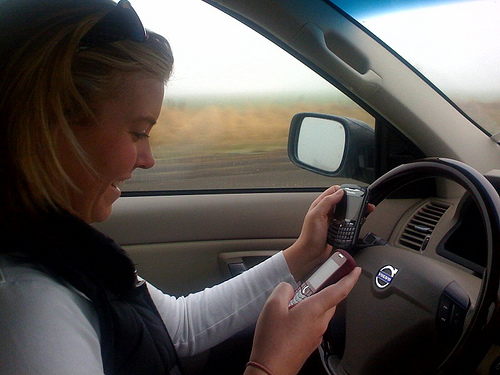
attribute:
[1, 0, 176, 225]
head —  woman's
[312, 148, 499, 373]
steering wheel —  car's, for steering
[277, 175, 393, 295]
phones — cell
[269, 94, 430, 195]
mirror —  of    car, to  side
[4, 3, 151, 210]
hair — blonde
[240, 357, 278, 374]
tie — hair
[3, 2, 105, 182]
hair — light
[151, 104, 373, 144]
grass — dead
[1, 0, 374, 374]
girl — smiling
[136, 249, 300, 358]
long sleeve —  long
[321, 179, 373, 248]
phone — black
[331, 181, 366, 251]
cellphone — red